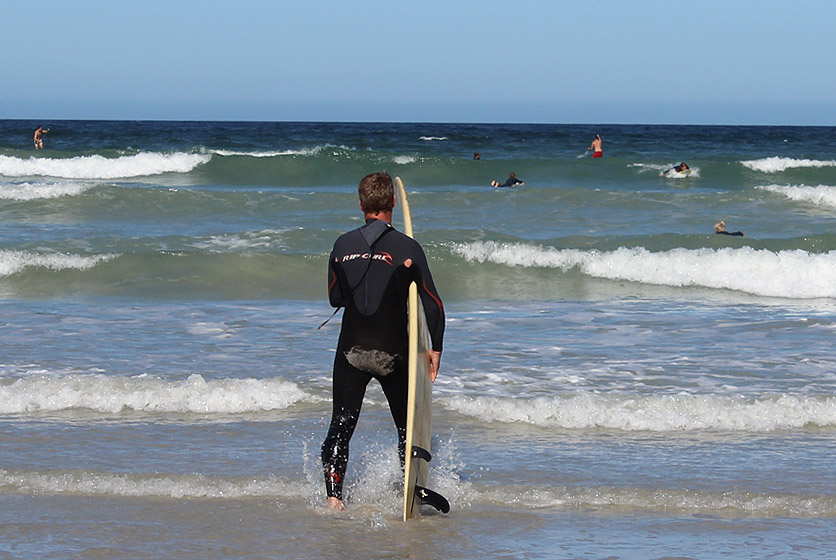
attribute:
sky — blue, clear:
[1, 1, 809, 125]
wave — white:
[1, 141, 379, 192]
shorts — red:
[589, 148, 608, 160]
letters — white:
[329, 247, 391, 269]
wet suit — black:
[320, 218, 450, 496]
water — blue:
[1, 124, 806, 557]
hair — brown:
[352, 167, 400, 214]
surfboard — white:
[388, 171, 448, 523]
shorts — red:
[589, 147, 611, 157]